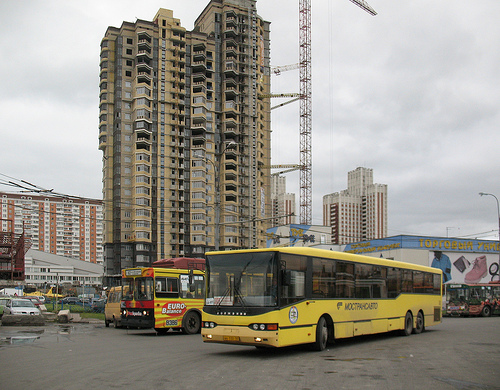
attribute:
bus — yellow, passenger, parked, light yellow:
[200, 247, 444, 352]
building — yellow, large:
[271, 173, 294, 225]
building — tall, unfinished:
[99, 2, 271, 307]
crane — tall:
[353, 0, 380, 16]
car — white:
[3, 299, 39, 323]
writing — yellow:
[421, 238, 499, 253]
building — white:
[310, 235, 500, 285]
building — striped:
[0, 195, 106, 264]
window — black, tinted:
[311, 258, 336, 297]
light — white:
[254, 337, 261, 342]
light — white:
[207, 334, 211, 340]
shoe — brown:
[465, 257, 488, 284]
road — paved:
[1, 315, 498, 389]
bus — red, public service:
[122, 257, 205, 333]